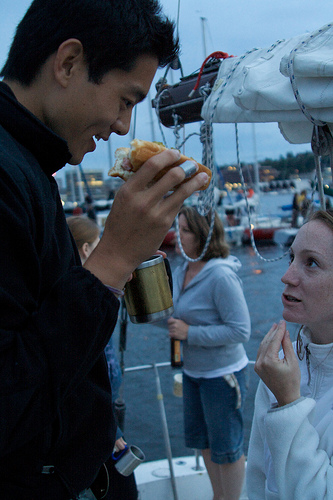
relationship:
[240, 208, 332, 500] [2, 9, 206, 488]
woman looking up at young man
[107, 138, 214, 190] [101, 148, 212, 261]
sandwich in hand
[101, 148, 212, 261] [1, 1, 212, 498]
hand of man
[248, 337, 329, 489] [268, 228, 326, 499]
white jacket worn by woman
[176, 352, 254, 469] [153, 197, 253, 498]
jeans worn by woman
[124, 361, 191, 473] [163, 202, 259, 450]
railing next to lady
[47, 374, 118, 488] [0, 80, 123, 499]
pockets on jacket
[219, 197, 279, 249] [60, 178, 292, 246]
boat on dock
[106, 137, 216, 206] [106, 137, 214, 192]
food in bun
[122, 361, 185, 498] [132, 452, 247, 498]
rail on boat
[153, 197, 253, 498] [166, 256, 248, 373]
woman wearing blue jacke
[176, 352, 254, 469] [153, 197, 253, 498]
jeans on a woman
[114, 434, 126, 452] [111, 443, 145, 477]
hand on a cup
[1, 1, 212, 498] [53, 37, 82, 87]
man has left ear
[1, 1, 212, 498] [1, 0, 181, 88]
man with hair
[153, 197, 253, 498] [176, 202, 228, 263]
woman with brown hair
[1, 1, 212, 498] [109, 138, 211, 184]
man eating a hot dog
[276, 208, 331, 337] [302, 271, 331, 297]
woman with freckles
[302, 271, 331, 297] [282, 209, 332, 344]
freckles on face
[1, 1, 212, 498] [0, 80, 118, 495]
man wearing a black fleece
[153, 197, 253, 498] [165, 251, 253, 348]
woman wearing coat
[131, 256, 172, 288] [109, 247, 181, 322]
coffee in thermos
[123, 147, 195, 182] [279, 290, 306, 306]
food in mouth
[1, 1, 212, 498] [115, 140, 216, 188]
man holding hotdog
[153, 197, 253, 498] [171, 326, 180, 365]
woman holding beer